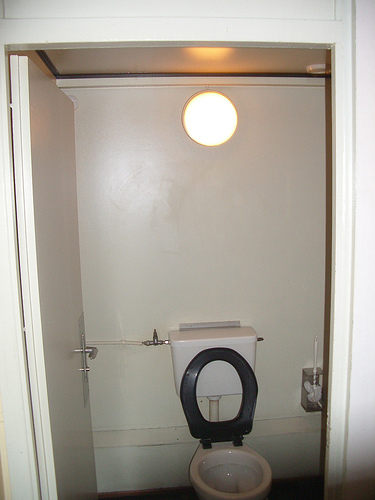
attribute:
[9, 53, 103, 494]
door — white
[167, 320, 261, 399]
tank — white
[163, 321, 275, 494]
toilet — white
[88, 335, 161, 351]
pipe — small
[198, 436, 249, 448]
hinges — black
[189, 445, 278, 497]
toilet — white